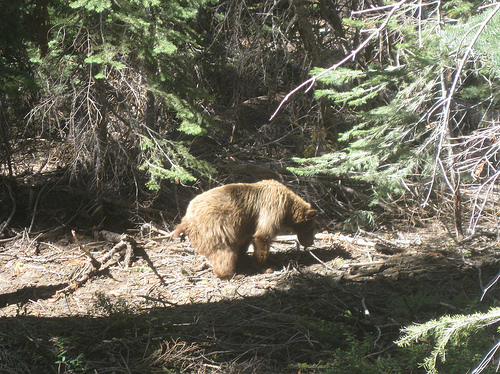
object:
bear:
[170, 179, 318, 280]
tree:
[44, 0, 218, 199]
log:
[68, 215, 161, 280]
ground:
[8, 116, 491, 372]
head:
[297, 205, 319, 247]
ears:
[305, 209, 319, 220]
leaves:
[156, 17, 185, 58]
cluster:
[164, 42, 176, 55]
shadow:
[257, 242, 354, 275]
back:
[201, 182, 277, 220]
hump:
[225, 187, 265, 204]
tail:
[169, 222, 185, 240]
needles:
[158, 265, 204, 302]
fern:
[45, 333, 92, 373]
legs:
[203, 229, 245, 280]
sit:
[169, 208, 243, 275]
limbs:
[60, 94, 139, 177]